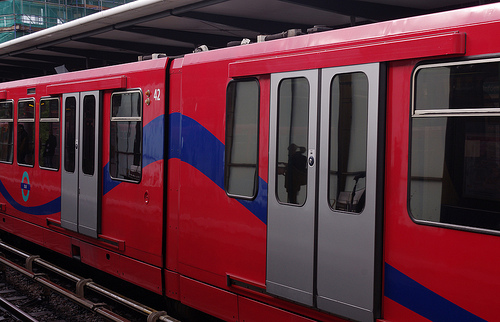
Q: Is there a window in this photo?
A: Yes, there is a window.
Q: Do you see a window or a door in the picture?
A: Yes, there is a window.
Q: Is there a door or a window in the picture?
A: Yes, there is a window.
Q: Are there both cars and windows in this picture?
A: Yes, there are both a window and a car.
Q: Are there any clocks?
A: No, there are no clocks.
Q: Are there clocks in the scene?
A: No, there are no clocks.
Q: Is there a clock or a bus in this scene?
A: No, there are no clocks or buses.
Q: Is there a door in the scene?
A: Yes, there is a door.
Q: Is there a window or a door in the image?
A: Yes, there is a door.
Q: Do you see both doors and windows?
A: Yes, there are both a door and windows.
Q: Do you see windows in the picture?
A: Yes, there is a window.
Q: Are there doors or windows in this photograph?
A: Yes, there is a window.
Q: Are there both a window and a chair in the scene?
A: No, there is a window but no chairs.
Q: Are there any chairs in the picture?
A: No, there are no chairs.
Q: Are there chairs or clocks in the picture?
A: No, there are no chairs or clocks.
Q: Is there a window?
A: Yes, there is a window.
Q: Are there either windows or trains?
A: Yes, there is a window.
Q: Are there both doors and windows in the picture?
A: Yes, there are both a window and doors.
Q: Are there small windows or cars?
A: Yes, there is a small window.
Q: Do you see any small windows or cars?
A: Yes, there is a small window.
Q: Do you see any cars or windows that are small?
A: Yes, the window is small.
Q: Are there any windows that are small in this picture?
A: Yes, there is a small window.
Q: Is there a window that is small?
A: Yes, there is a window that is small.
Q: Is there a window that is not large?
A: Yes, there is a small window.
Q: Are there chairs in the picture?
A: No, there are no chairs.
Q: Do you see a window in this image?
A: Yes, there is a window.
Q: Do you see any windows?
A: Yes, there is a window.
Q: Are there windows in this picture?
A: Yes, there is a window.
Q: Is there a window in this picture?
A: Yes, there is a window.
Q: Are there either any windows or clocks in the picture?
A: Yes, there is a window.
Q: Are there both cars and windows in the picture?
A: Yes, there are both a window and a car.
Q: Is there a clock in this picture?
A: No, there are no clocks.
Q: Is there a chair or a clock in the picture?
A: No, there are no clocks or chairs.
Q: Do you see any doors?
A: Yes, there is a door.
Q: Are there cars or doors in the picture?
A: Yes, there is a door.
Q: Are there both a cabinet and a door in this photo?
A: No, there is a door but no cabinets.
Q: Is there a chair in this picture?
A: No, there are no chairs.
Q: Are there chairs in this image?
A: No, there are no chairs.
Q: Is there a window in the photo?
A: Yes, there is a window.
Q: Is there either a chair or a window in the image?
A: Yes, there is a window.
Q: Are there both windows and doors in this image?
A: Yes, there are both a window and a door.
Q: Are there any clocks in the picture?
A: No, there are no clocks.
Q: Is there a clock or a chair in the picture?
A: No, there are no clocks or chairs.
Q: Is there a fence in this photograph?
A: No, there are no fences.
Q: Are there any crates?
A: No, there are no crates.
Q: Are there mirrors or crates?
A: No, there are no crates or mirrors.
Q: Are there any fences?
A: No, there are no fences.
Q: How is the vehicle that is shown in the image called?
A: The vehicle is a car.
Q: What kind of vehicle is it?
A: The vehicle is a car.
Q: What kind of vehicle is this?
A: This is a car.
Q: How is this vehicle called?
A: This is a car.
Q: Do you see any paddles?
A: No, there are no paddles.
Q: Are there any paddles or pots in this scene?
A: No, there are no paddles or pots.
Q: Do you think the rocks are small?
A: Yes, the rocks are small.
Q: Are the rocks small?
A: Yes, the rocks are small.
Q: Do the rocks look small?
A: Yes, the rocks are small.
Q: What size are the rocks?
A: The rocks are small.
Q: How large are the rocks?
A: The rocks are small.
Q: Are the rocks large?
A: No, the rocks are small.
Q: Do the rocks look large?
A: No, the rocks are small.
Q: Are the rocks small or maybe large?
A: The rocks are small.